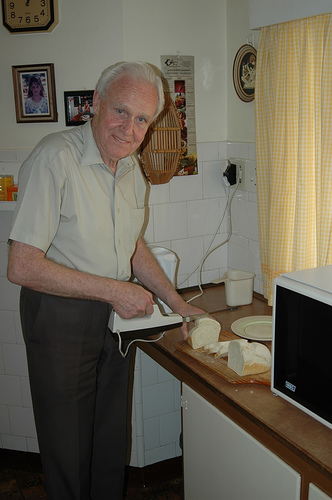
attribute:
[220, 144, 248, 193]
outlet — electrical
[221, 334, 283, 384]
bread — cut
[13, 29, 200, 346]
man — smiling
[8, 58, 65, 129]
picture — round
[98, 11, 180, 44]
wall — white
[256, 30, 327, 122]
curtain — yellow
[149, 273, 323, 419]
counter — wooden